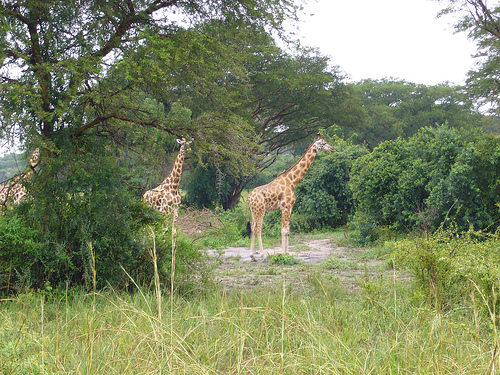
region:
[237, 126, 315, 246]
Tall giraffe standing on grass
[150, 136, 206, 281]
Tall giraffe standing on grass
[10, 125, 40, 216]
Tall giraffe standing on grass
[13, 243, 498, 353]
Tall green grass in foreground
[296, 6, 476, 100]
gray sky pearing through trees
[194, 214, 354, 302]
patch of gray dirt in grass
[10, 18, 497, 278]
tall green trees in forest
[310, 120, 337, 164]
head of tall giraffe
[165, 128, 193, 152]
head of tall giraffe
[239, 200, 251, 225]
tail of tall giraffe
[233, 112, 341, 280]
The giraffe is standing.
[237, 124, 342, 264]
The giraffe is tall.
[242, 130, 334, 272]
Giraffe standing on dirt.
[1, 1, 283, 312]
The tree is green.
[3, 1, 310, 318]
The tree is leafy.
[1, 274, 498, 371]
The grass is tall.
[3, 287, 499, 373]
The grass is overgrown.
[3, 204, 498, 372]
Weeds are turning brown.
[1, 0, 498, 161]
The sky is clear.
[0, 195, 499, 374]
The ground is dry.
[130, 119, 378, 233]
two giraffes in the wild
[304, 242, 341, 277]
brown dirt under animals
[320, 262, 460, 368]
green grass near the giraffes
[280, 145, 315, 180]
neck of the giraffe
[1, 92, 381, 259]
three different giraffes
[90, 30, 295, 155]
trees next to the animals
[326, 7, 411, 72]
white sky above the land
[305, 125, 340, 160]
head of the animal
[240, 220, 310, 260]
legs of the animal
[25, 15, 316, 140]
many different trees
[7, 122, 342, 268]
three giraffes standing in grass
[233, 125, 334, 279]
one giraffe standing in grass looking straight ahead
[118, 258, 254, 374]
tall green blades of grass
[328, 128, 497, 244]
tall green shrubs and brush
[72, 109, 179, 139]
brown limbs of tree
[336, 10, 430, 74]
clear white sky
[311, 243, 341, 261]
patch of tan dirt on ground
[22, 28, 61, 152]
brown tree trunk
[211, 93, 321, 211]
brown tree trunk and branches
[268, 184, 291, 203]
brown and tan spots on giraffe fur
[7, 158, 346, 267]
three giraffes in field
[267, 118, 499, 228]
green and thick bushes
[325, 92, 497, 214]
bushes are leafy and green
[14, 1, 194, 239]
tall tree in front of giraffes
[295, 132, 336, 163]
giraffe has white face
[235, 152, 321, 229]
giraffe has brown and tan spots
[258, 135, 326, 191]
giraffe has long neck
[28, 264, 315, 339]
grass is brown and thin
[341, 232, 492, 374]
grass is green and thick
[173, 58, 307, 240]
tall tree behind giraffes